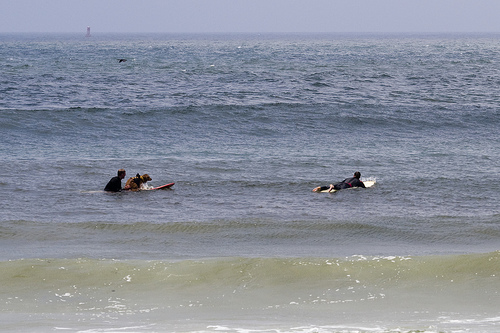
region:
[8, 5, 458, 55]
the sky is blue.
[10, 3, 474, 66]
no clouds in the sky.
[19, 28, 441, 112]
the water is lbue.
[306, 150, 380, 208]
the surf board is white.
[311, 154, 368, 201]
the wetsuit is black.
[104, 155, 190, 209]
dog on a surf board.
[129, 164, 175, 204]
surf board is red.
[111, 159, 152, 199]
dog is brown.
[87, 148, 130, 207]
man's wetsuit is black.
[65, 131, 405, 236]
only two surf boards are visible.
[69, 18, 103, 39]
a floater in the water in the back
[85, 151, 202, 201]
a man teaching a dog to surf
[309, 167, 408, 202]
a man about to surf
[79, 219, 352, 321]
the water in the fore front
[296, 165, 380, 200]
the man on the surfboard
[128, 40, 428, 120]
the beautiful ocean water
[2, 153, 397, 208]
two men and a dog surfing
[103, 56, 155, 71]
a bird flying in the background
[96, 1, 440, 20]
the beautiful horizon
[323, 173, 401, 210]
a man on a white surf board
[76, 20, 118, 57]
A red and grey buoy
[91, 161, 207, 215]
A man with a brown dog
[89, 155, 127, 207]
A man in black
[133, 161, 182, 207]
A red surfboard in the water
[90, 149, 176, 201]
The man and dog are on the surfboard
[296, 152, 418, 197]
A man in a black swimsuit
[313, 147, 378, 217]
The surfboard is white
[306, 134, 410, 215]
The man lies on the surfboard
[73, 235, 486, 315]
A wave is about to break onto shore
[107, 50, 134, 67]
A black bird flies over the water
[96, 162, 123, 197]
a person in water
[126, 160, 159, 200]
a person in water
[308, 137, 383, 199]
a person in water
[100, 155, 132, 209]
a person surfing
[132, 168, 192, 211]
a person surfing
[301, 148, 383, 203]
a person surfing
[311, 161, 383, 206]
a person in a suit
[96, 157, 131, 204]
a person in a suit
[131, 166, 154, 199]
a person in a suit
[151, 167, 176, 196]
a red surfboard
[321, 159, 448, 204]
a man paddling on a surfboard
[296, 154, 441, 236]
a man wearing a black wetsuit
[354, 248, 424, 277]
thin white foam on the surface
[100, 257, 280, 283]
a small gentle wave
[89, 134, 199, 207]
a man pushing his dog on a surfboard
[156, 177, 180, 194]
a red surfboard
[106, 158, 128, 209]
a man wearing a black shirt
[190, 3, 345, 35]
the clear blue sky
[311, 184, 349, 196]
bare feet facing upwards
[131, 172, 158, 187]
a brown dog in the ocean